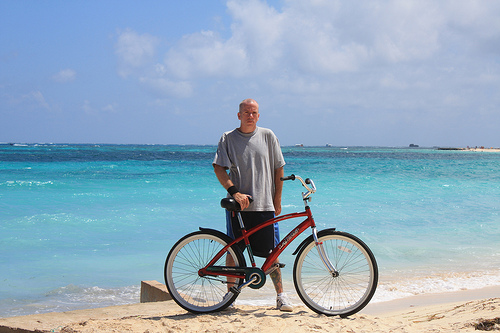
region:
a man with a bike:
[189, 85, 411, 318]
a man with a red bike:
[181, 196, 421, 323]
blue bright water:
[58, 91, 161, 265]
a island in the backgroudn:
[405, 108, 497, 182]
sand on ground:
[118, 312, 187, 331]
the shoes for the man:
[264, 293, 301, 318]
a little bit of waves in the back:
[25, 164, 64, 222]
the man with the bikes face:
[238, 98, 273, 127]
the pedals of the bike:
[230, 255, 304, 300]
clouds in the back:
[210, 28, 433, 98]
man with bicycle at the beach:
[128, 54, 456, 331]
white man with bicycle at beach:
[165, 77, 391, 331]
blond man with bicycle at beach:
[160, 80, 409, 325]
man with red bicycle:
[176, 76, 361, 331]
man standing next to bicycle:
[169, 77, 359, 314]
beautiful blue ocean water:
[21, 146, 141, 263]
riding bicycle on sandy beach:
[135, 82, 433, 331]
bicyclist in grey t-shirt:
[151, 90, 383, 317]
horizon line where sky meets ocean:
[22, 107, 169, 199]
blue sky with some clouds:
[35, 70, 177, 140]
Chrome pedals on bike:
[234, 256, 284, 305]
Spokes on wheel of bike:
[334, 253, 366, 300]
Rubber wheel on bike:
[289, 232, 393, 321]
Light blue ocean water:
[12, 185, 107, 238]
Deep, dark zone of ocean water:
[5, 143, 119, 171]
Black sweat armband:
[222, 181, 241, 201]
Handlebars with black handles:
[272, 166, 329, 206]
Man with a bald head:
[215, 93, 279, 143]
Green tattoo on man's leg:
[264, 261, 290, 323]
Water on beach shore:
[400, 270, 489, 323]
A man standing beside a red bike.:
[157, 92, 392, 324]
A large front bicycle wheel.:
[284, 223, 379, 325]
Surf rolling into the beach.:
[397, 265, 497, 302]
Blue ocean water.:
[18, 160, 149, 251]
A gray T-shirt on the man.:
[211, 121, 288, 223]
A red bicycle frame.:
[196, 203, 324, 282]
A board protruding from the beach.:
[133, 273, 178, 304]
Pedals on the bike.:
[228, 259, 289, 299]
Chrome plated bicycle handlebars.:
[276, 170, 325, 207]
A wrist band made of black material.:
[218, 181, 243, 198]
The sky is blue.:
[55, 27, 439, 297]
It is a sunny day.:
[59, 59, 404, 129]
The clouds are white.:
[135, 45, 415, 76]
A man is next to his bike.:
[107, 42, 407, 313]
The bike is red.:
[121, 221, 431, 283]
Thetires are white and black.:
[121, 218, 333, 330]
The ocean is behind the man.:
[61, 132, 169, 234]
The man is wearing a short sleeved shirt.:
[172, 120, 299, 205]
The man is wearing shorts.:
[201, 196, 292, 255]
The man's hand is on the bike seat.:
[201, 82, 292, 224]